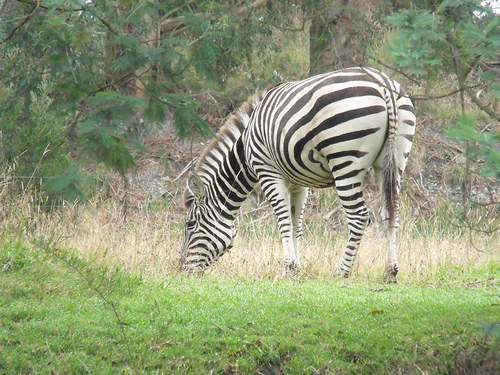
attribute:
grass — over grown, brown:
[413, 236, 471, 263]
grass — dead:
[1, 179, 183, 276]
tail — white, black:
[383, 152, 401, 237]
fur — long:
[380, 144, 400, 233]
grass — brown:
[5, 233, 498, 373]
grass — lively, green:
[36, 114, 488, 355]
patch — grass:
[421, 347, 498, 371]